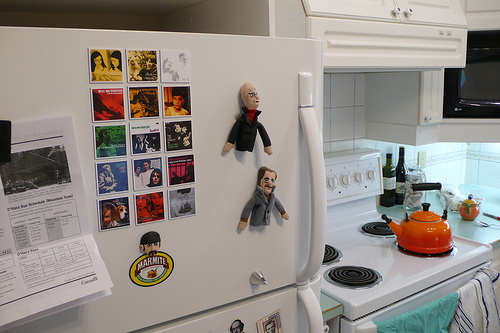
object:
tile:
[330, 73, 355, 108]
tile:
[467, 158, 479, 185]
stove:
[319, 147, 491, 320]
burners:
[359, 222, 395, 238]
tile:
[331, 106, 356, 140]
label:
[395, 181, 406, 193]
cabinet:
[275, 0, 470, 70]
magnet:
[128, 230, 175, 285]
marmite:
[129, 251, 175, 287]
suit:
[227, 106, 272, 152]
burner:
[323, 265, 383, 289]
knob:
[342, 174, 351, 185]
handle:
[293, 72, 327, 288]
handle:
[295, 284, 325, 333]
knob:
[368, 170, 376, 179]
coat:
[241, 185, 286, 226]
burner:
[394, 241, 457, 258]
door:
[0, 27, 329, 333]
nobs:
[327, 169, 379, 188]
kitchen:
[0, 0, 500, 333]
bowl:
[459, 194, 484, 221]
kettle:
[381, 181, 454, 254]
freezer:
[1, 24, 330, 333]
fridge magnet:
[221, 83, 274, 156]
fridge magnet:
[236, 166, 289, 230]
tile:
[355, 73, 365, 106]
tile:
[322, 74, 331, 108]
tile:
[355, 106, 367, 138]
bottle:
[395, 146, 407, 205]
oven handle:
[357, 271, 487, 333]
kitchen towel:
[372, 291, 457, 333]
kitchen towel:
[448, 267, 500, 333]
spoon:
[477, 220, 500, 227]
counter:
[348, 207, 499, 241]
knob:
[328, 176, 338, 188]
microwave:
[442, 30, 500, 120]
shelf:
[440, 118, 500, 125]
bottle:
[380, 153, 397, 207]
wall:
[323, 70, 497, 197]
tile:
[445, 159, 466, 185]